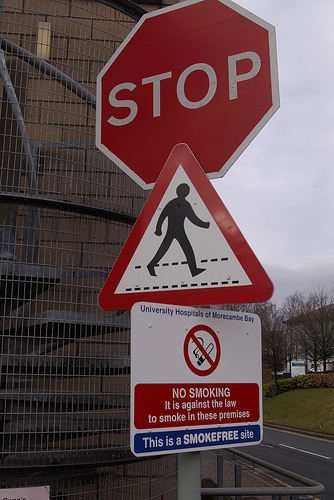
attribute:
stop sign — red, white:
[96, 1, 280, 194]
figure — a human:
[143, 183, 212, 278]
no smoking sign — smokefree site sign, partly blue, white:
[131, 301, 263, 457]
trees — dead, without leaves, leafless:
[260, 289, 330, 381]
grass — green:
[264, 384, 333, 435]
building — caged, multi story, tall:
[2, 1, 176, 500]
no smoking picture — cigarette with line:
[183, 325, 222, 377]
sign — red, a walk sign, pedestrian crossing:
[96, 141, 275, 314]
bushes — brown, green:
[264, 373, 333, 400]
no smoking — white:
[171, 384, 232, 401]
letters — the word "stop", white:
[109, 49, 261, 127]